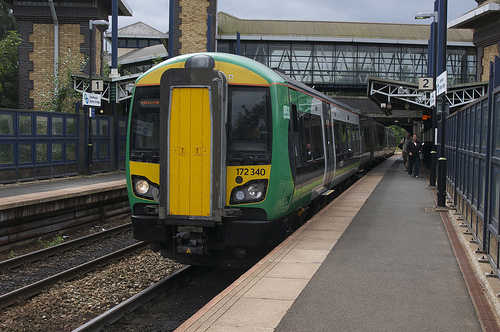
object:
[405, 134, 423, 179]
people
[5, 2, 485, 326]
outdoors